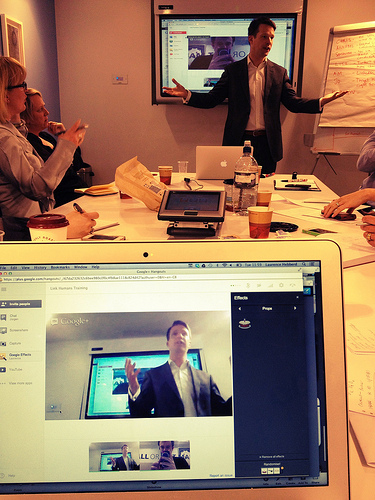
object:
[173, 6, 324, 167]
man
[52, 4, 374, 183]
wall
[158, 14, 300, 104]
screen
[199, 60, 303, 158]
suit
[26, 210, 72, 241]
cup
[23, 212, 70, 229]
lid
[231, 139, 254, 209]
bottle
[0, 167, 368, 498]
table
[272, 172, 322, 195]
clipboard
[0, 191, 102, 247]
person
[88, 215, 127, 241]
paper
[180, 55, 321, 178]
wedding band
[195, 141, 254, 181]
laptop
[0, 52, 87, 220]
woman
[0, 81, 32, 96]
glasses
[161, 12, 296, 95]
screen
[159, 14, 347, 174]
speaker